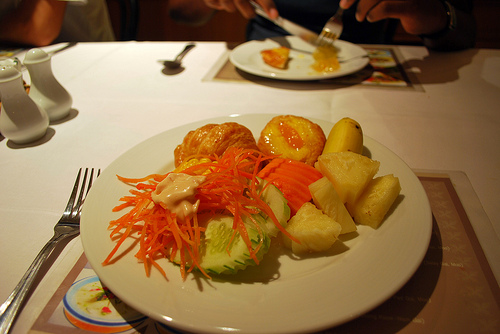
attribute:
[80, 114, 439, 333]
plate — round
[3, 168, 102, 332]
fork — metal, silver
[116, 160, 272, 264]
carrots — orange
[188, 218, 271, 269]
cucumber slices — green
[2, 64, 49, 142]
salt shaker — white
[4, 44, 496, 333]
tablecloth — white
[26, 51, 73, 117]
salt shaker — white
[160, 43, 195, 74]
spoon — silver